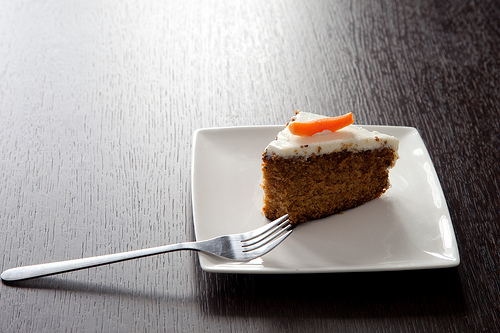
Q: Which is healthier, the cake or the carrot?
A: The carrot is healthier than the cake.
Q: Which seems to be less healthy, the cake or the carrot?
A: The cake is less healthy than the carrot.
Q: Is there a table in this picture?
A: Yes, there is a table.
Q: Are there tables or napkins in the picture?
A: Yes, there is a table.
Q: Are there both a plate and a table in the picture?
A: Yes, there are both a table and a plate.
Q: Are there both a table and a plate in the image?
A: Yes, there are both a table and a plate.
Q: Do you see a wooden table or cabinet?
A: Yes, there is a wood table.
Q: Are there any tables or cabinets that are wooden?
A: Yes, the table is wooden.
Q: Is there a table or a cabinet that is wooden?
A: Yes, the table is wooden.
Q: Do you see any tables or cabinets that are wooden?
A: Yes, the table is wooden.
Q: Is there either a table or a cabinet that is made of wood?
A: Yes, the table is made of wood.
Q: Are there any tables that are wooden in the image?
A: Yes, there is a wood table.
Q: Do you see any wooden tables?
A: Yes, there is a wood table.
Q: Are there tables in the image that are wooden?
A: Yes, there is a table that is wooden.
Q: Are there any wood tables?
A: Yes, there is a table that is made of wood.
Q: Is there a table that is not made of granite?
A: Yes, there is a table that is made of wood.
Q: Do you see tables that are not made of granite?
A: Yes, there is a table that is made of wood.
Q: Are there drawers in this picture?
A: No, there are no drawers.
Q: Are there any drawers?
A: No, there are no drawers.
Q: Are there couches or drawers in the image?
A: No, there are no drawers or couches.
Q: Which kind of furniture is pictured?
A: The furniture is a table.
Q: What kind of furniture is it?
A: The piece of furniture is a table.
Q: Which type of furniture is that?
A: This is a table.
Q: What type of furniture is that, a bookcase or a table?
A: This is a table.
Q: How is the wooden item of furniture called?
A: The piece of furniture is a table.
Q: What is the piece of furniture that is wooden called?
A: The piece of furniture is a table.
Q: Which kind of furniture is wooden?
A: The furniture is a table.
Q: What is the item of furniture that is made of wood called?
A: The piece of furniture is a table.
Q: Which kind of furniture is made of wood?
A: The furniture is a table.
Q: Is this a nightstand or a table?
A: This is a table.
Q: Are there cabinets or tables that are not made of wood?
A: No, there is a table but it is made of wood.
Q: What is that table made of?
A: The table is made of wood.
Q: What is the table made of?
A: The table is made of wood.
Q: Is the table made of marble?
A: No, the table is made of wood.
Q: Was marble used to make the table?
A: No, the table is made of wood.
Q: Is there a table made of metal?
A: No, there is a table but it is made of wood.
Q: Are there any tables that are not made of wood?
A: No, there is a table but it is made of wood.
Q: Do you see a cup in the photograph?
A: No, there are no cups.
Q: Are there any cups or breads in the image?
A: No, there are no cups or breads.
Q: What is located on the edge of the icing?
A: The crumbs are on the edge of the icing.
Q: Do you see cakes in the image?
A: Yes, there is a cake.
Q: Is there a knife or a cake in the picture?
A: Yes, there is a cake.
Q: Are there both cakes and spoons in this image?
A: No, there is a cake but no spoons.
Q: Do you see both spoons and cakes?
A: No, there is a cake but no spoons.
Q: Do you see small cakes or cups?
A: Yes, there is a small cake.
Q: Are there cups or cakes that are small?
A: Yes, the cake is small.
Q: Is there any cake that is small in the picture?
A: Yes, there is a small cake.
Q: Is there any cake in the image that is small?
A: Yes, there is a cake that is small.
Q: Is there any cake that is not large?
A: Yes, there is a small cake.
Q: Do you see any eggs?
A: No, there are no eggs.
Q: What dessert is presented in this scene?
A: The dessert is a cake.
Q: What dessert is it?
A: The dessert is a cake.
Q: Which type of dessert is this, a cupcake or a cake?
A: This is a cake.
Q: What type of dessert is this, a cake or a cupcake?
A: This is a cake.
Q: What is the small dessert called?
A: The dessert is a cake.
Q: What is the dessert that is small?
A: The dessert is a cake.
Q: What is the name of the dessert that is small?
A: The dessert is a cake.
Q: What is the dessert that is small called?
A: The dessert is a cake.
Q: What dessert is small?
A: The dessert is a cake.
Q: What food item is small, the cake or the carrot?
A: The cake is small.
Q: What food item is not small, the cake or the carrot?
A: The carrot is not small.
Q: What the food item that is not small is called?
A: The food item is a carrot.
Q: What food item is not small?
A: The food item is a carrot.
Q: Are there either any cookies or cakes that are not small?
A: No, there is a cake but it is small.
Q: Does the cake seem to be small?
A: Yes, the cake is small.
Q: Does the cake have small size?
A: Yes, the cake is small.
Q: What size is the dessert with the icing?
A: The cake is small.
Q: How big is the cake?
A: The cake is small.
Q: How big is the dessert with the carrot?
A: The cake is small.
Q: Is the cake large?
A: No, the cake is small.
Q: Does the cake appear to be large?
A: No, the cake is small.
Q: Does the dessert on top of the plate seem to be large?
A: No, the cake is small.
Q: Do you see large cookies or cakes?
A: No, there is a cake but it is small.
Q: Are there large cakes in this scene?
A: No, there is a cake but it is small.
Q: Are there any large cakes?
A: No, there is a cake but it is small.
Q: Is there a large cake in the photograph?
A: No, there is a cake but it is small.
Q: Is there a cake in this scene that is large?
A: No, there is a cake but it is small.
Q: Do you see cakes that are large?
A: No, there is a cake but it is small.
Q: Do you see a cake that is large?
A: No, there is a cake but it is small.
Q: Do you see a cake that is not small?
A: No, there is a cake but it is small.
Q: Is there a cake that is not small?
A: No, there is a cake but it is small.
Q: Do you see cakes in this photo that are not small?
A: No, there is a cake but it is small.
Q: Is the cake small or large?
A: The cake is small.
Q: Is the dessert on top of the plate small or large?
A: The cake is small.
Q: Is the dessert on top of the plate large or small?
A: The cake is small.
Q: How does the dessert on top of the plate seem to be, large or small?
A: The cake is small.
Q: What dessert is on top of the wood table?
A: The dessert is a cake.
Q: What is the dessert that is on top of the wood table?
A: The dessert is a cake.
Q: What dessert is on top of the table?
A: The dessert is a cake.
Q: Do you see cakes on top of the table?
A: Yes, there is a cake on top of the table.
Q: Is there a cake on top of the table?
A: Yes, there is a cake on top of the table.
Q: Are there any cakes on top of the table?
A: Yes, there is a cake on top of the table.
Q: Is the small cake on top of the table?
A: Yes, the cake is on top of the table.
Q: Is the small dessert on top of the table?
A: Yes, the cake is on top of the table.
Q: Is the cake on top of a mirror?
A: No, the cake is on top of the table.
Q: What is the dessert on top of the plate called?
A: The dessert is a cake.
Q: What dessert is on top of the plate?
A: The dessert is a cake.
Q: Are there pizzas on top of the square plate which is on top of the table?
A: No, there is a cake on top of the plate.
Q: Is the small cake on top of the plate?
A: Yes, the cake is on top of the plate.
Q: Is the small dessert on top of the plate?
A: Yes, the cake is on top of the plate.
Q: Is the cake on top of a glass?
A: No, the cake is on top of the plate.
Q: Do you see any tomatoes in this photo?
A: No, there are no tomatoes.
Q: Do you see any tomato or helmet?
A: No, there are no tomatoes or helmets.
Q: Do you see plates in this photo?
A: Yes, there is a plate.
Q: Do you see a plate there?
A: Yes, there is a plate.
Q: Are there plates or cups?
A: Yes, there is a plate.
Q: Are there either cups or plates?
A: Yes, there is a plate.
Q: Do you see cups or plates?
A: Yes, there is a plate.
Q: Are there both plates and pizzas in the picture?
A: No, there is a plate but no pizzas.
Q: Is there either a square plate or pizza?
A: Yes, there is a square plate.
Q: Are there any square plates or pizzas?
A: Yes, there is a square plate.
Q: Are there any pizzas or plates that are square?
A: Yes, the plate is square.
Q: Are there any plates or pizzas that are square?
A: Yes, the plate is square.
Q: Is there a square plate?
A: Yes, there is a square plate.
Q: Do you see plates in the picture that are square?
A: Yes, there is a plate that is square.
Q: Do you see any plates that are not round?
A: Yes, there is a square plate.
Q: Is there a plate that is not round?
A: Yes, there is a square plate.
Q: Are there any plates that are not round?
A: Yes, there is a square plate.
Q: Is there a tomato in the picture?
A: No, there are no tomatoes.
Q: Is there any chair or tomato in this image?
A: No, there are no tomatoes or chairs.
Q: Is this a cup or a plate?
A: This is a plate.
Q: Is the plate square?
A: Yes, the plate is square.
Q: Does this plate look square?
A: Yes, the plate is square.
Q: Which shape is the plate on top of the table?
A: The plate is square.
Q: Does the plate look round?
A: No, the plate is square.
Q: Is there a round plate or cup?
A: No, there is a plate but it is square.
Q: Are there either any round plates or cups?
A: No, there is a plate but it is square.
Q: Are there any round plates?
A: No, there is a plate but it is square.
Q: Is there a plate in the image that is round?
A: No, there is a plate but it is square.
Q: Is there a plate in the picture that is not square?
A: No, there is a plate but it is square.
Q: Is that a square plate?
A: Yes, that is a square plate.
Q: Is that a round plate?
A: No, that is a square plate.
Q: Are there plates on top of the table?
A: Yes, there is a plate on top of the table.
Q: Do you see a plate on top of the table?
A: Yes, there is a plate on top of the table.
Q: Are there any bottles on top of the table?
A: No, there is a plate on top of the table.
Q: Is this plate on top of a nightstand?
A: No, the plate is on top of a table.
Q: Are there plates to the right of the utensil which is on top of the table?
A: Yes, there is a plate to the right of the fork.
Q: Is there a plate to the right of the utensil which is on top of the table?
A: Yes, there is a plate to the right of the fork.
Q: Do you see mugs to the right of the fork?
A: No, there is a plate to the right of the fork.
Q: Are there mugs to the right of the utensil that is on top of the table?
A: No, there is a plate to the right of the fork.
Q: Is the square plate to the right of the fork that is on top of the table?
A: Yes, the plate is to the right of the fork.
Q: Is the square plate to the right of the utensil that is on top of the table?
A: Yes, the plate is to the right of the fork.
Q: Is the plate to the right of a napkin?
A: No, the plate is to the right of the fork.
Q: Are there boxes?
A: No, there are no boxes.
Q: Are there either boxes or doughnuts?
A: No, there are no boxes or doughnuts.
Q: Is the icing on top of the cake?
A: Yes, the icing is on top of the cake.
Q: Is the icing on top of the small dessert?
A: Yes, the icing is on top of the cake.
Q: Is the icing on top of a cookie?
A: No, the icing is on top of the cake.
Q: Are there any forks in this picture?
A: Yes, there is a fork.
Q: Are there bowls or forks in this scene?
A: Yes, there is a fork.